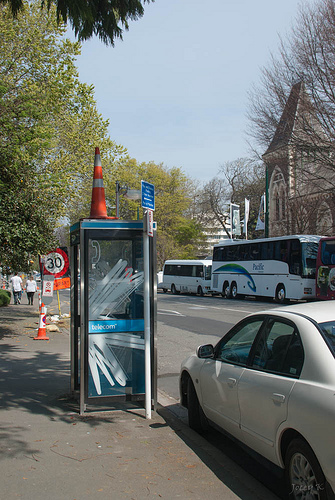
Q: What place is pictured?
A: It is a road.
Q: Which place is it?
A: It is a road.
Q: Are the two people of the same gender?
A: No, they are both male and female.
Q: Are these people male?
A: No, they are both male and female.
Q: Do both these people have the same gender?
A: No, they are both male and female.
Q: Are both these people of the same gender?
A: No, they are both male and female.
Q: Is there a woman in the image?
A: Yes, there is a woman.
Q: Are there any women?
A: Yes, there is a woman.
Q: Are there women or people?
A: Yes, there is a woman.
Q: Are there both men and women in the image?
A: Yes, there are both a woman and a man.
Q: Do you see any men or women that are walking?
A: Yes, the woman is walking.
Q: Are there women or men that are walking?
A: Yes, the woman is walking.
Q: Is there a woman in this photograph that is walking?
A: Yes, there is a woman that is walking.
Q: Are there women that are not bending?
A: Yes, there is a woman that is walking.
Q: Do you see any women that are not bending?
A: Yes, there is a woman that is walking .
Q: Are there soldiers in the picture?
A: No, there are no soldiers.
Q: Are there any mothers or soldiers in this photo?
A: No, there are no soldiers or mothers.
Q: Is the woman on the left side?
A: Yes, the woman is on the left of the image.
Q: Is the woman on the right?
A: No, the woman is on the left of the image.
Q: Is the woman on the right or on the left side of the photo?
A: The woman is on the left of the image.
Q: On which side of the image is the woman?
A: The woman is on the left of the image.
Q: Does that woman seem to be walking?
A: Yes, the woman is walking.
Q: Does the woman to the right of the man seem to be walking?
A: Yes, the woman is walking.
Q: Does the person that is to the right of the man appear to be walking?
A: Yes, the woman is walking.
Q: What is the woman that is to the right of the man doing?
A: The woman is walking.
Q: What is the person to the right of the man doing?
A: The woman is walking.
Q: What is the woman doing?
A: The woman is walking.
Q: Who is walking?
A: The woman is walking.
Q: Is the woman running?
A: No, the woman is walking.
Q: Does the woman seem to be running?
A: No, the woman is walking.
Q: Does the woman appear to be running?
A: No, the woman is walking.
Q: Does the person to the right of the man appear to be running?
A: No, the woman is walking.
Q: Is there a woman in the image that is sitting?
A: No, there is a woman but she is walking.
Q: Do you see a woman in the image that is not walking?
A: No, there is a woman but she is walking.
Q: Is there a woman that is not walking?
A: No, there is a woman but she is walking.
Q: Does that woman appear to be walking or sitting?
A: The woman is walking.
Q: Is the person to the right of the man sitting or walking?
A: The woman is walking.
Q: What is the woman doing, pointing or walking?
A: The woman is walking.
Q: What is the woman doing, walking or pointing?
A: The woman is walking.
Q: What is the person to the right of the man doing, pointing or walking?
A: The woman is walking.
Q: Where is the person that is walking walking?
A: The woman is walking on the pavement.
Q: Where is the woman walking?
A: The woman is walking on the pavement.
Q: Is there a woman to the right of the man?
A: Yes, there is a woman to the right of the man.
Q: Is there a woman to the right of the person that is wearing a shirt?
A: Yes, there is a woman to the right of the man.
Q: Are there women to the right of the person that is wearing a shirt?
A: Yes, there is a woman to the right of the man.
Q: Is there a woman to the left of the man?
A: No, the woman is to the right of the man.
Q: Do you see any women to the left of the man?
A: No, the woman is to the right of the man.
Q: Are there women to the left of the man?
A: No, the woman is to the right of the man.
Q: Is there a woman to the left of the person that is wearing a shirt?
A: No, the woman is to the right of the man.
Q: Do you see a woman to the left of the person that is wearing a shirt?
A: No, the woman is to the right of the man.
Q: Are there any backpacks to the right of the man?
A: No, there is a woman to the right of the man.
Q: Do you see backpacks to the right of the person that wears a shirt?
A: No, there is a woman to the right of the man.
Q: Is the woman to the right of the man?
A: Yes, the woman is to the right of the man.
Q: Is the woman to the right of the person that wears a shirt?
A: Yes, the woman is to the right of the man.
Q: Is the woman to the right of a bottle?
A: No, the woman is to the right of the man.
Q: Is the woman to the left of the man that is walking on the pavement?
A: No, the woman is to the right of the man.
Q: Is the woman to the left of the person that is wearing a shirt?
A: No, the woman is to the right of the man.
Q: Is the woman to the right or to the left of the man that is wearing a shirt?
A: The woman is to the right of the man.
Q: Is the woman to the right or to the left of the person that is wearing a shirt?
A: The woman is to the right of the man.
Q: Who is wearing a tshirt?
A: The woman is wearing a tshirt.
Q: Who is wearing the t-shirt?
A: The woman is wearing a tshirt.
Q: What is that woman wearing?
A: The woman is wearing a t-shirt.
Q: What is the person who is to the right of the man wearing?
A: The woman is wearing a t-shirt.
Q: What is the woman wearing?
A: The woman is wearing a t-shirt.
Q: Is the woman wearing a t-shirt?
A: Yes, the woman is wearing a t-shirt.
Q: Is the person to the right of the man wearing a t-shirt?
A: Yes, the woman is wearing a t-shirt.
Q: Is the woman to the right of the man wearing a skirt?
A: No, the woman is wearing a t-shirt.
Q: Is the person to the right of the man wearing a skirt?
A: No, the woman is wearing a t-shirt.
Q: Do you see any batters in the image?
A: No, there are no batters.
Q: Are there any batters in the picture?
A: No, there are no batters.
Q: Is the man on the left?
A: Yes, the man is on the left of the image.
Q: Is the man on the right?
A: No, the man is on the left of the image.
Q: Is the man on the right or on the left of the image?
A: The man is on the left of the image.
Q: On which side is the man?
A: The man is on the left of the image.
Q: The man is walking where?
A: The man is walking on the pavement.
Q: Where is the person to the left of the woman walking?
A: The man is walking on the pavement.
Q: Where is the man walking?
A: The man is walking on the pavement.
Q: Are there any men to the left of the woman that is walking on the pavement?
A: Yes, there is a man to the left of the woman.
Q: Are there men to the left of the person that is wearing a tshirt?
A: Yes, there is a man to the left of the woman.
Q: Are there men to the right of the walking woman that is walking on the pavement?
A: No, the man is to the left of the woman.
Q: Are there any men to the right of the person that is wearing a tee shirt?
A: No, the man is to the left of the woman.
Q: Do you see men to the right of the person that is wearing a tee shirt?
A: No, the man is to the left of the woman.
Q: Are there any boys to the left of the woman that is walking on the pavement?
A: No, there is a man to the left of the woman.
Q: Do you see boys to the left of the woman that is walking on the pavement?
A: No, there is a man to the left of the woman.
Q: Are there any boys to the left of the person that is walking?
A: No, there is a man to the left of the woman.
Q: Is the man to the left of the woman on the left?
A: Yes, the man is to the left of the woman.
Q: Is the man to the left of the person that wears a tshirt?
A: Yes, the man is to the left of the woman.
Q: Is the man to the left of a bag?
A: No, the man is to the left of the woman.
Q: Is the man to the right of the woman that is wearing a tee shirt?
A: No, the man is to the left of the woman.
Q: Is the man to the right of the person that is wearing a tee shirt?
A: No, the man is to the left of the woman.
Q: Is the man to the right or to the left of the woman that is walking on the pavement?
A: The man is to the left of the woman.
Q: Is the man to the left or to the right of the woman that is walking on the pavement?
A: The man is to the left of the woman.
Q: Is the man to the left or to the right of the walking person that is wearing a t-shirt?
A: The man is to the left of the woman.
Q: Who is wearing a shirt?
A: The man is wearing a shirt.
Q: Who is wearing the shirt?
A: The man is wearing a shirt.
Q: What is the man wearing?
A: The man is wearing a shirt.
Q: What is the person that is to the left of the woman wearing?
A: The man is wearing a shirt.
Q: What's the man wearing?
A: The man is wearing a shirt.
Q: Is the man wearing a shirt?
A: Yes, the man is wearing a shirt.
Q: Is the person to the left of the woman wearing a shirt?
A: Yes, the man is wearing a shirt.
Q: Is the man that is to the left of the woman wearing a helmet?
A: No, the man is wearing a shirt.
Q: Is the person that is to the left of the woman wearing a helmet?
A: No, the man is wearing a shirt.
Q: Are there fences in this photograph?
A: No, there are no fences.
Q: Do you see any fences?
A: No, there are no fences.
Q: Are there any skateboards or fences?
A: No, there are no fences or skateboards.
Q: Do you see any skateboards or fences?
A: No, there are no fences or skateboards.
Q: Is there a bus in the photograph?
A: Yes, there are buses.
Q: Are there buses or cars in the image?
A: Yes, there are buses.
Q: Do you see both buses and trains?
A: No, there are buses but no trains.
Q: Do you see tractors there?
A: No, there are no tractors.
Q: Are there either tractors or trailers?
A: No, there are no tractors or trailers.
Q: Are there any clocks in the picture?
A: No, there are no clocks.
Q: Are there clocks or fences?
A: No, there are no clocks or fences.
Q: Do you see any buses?
A: Yes, there is a bus.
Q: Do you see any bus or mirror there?
A: Yes, there is a bus.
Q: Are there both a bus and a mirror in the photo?
A: Yes, there are both a bus and a mirror.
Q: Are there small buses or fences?
A: Yes, there is a small bus.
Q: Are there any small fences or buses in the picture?
A: Yes, there is a small bus.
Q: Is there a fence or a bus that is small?
A: Yes, the bus is small.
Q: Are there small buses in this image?
A: Yes, there is a small bus.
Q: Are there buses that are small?
A: Yes, there is a bus that is small.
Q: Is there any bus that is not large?
A: Yes, there is a small bus.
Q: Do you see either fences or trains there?
A: No, there are no fences or trains.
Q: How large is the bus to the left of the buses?
A: The bus is small.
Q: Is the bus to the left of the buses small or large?
A: The bus is small.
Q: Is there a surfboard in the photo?
A: No, there are no surfboards.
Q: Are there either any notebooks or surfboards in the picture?
A: No, there are no surfboards or notebooks.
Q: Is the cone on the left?
A: Yes, the cone is on the left of the image.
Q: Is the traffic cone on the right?
A: No, the traffic cone is on the left of the image.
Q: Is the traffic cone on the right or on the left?
A: The traffic cone is on the left of the image.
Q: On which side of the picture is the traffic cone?
A: The traffic cone is on the left of the image.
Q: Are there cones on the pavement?
A: Yes, there is a cone on the pavement.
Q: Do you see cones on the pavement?
A: Yes, there is a cone on the pavement.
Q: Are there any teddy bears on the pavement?
A: No, there is a cone on the pavement.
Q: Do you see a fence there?
A: No, there are no fences.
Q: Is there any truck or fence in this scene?
A: No, there are no fences or trucks.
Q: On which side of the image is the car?
A: The car is on the right of the image.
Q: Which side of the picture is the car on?
A: The car is on the right of the image.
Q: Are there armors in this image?
A: No, there are no armors.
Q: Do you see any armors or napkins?
A: No, there are no armors or napkins.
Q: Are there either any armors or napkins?
A: No, there are no armors or napkins.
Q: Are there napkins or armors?
A: No, there are no armors or napkins.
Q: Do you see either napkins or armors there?
A: No, there are no armors or napkins.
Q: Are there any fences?
A: No, there are no fences.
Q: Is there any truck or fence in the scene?
A: No, there are no fences or trucks.